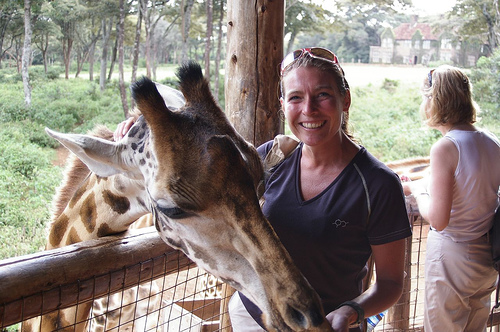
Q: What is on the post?
A: Wood.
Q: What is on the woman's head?
A: Sunglasses.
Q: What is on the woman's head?
A: Sunglasses.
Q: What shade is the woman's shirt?
A: White.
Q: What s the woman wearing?
A: White tank top.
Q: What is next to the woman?
A: A giraffe.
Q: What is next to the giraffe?
A: A woman.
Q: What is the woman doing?
A: Smiling.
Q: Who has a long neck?
A: The giraffe.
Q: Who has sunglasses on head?
A: Woman touching giraffe.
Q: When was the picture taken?
A: During the daytime.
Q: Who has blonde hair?
A: Woman on right.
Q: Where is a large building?
A: In the far distance.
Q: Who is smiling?
A: Woman with giraffe.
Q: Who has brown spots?
A: The giraffe.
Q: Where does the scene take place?
A: At a conservatory.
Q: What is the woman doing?
A: Petting giraffe.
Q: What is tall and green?
A: Trees.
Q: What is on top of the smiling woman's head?
A: Sunglasses.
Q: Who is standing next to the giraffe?
A: A woman with glasses on her head.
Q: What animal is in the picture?
A: A giraffe.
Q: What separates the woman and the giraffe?
A: A fence.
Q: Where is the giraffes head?
A: Leaning over the fence.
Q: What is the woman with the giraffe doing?
A: Smiling.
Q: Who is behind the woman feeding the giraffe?
A: Woman with a sleeveless top.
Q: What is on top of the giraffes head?
A: Horns.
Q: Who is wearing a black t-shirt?
A: The woman feeding the giraffe.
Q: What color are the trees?
A: Green.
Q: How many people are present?
A: Two.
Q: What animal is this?
A: Giraffe.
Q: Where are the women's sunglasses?
A: On their head.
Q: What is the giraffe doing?
A: Eating from her hand.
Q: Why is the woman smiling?
A: She is happy.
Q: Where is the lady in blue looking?
A: At the camera.